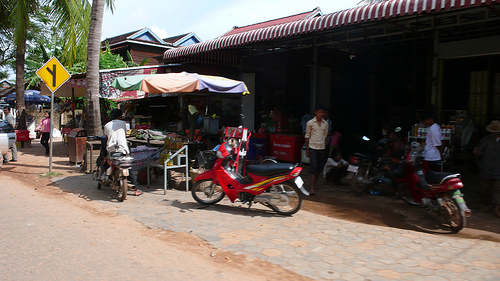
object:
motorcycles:
[353, 159, 471, 230]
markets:
[429, 10, 498, 163]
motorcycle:
[188, 146, 309, 215]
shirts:
[422, 123, 445, 164]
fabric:
[161, 0, 499, 61]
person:
[95, 109, 141, 195]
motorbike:
[96, 153, 127, 202]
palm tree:
[78, 1, 108, 138]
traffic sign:
[32, 57, 70, 93]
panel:
[101, 63, 196, 99]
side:
[75, 101, 500, 235]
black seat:
[246, 163, 295, 177]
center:
[63, 157, 500, 281]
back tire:
[262, 180, 305, 216]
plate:
[293, 176, 306, 189]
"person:
[34, 111, 53, 157]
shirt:
[36, 117, 52, 132]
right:
[245, 0, 499, 281]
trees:
[49, 0, 113, 136]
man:
[301, 108, 332, 197]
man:
[419, 116, 444, 183]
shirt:
[305, 117, 329, 151]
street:
[0, 126, 500, 281]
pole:
[48, 92, 55, 177]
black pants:
[423, 169, 455, 185]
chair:
[144, 145, 191, 194]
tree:
[0, 1, 57, 141]